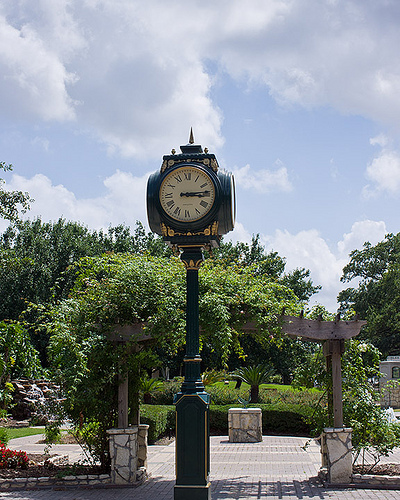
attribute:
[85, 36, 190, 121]
cloud — fluffy, white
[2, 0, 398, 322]
sky — blue , bright 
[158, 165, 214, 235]
clock — round, white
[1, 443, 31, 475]
flowers — Red 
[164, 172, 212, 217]
numerals — black, roman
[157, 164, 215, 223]
clock — green, metal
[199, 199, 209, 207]
number — in the picture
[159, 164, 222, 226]
clock — big 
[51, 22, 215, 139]
clouds — white 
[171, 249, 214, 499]
pole — green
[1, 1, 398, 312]
skies — clear , blue 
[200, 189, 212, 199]
number 3 — in the picture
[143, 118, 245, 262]
cube — rounded 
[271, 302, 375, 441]
structure — wooden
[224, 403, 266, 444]
square block — stone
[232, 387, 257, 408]
green sculpture — metal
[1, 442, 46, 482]
flowers — red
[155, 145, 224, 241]
clock — round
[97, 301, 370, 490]
arbor — wooden 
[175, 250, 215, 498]
pole — green, metal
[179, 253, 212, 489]
trim — gold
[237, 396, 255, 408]
statue — brick 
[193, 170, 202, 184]
roman numeral — in the picture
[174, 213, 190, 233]
trim — gold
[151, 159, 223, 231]
clockface — white